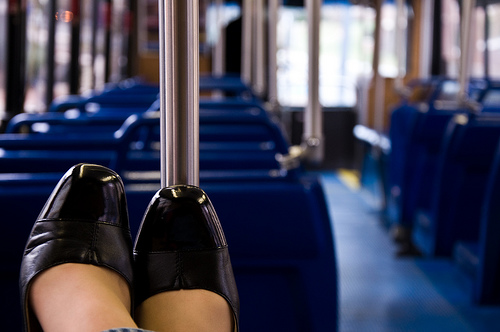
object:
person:
[224, 16, 241, 74]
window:
[276, 7, 378, 107]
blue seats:
[122, 172, 338, 332]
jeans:
[93, 328, 155, 330]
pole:
[459, 0, 476, 94]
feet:
[28, 263, 136, 332]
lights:
[278, 9, 370, 105]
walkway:
[315, 170, 499, 332]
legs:
[395, 227, 423, 255]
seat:
[429, 85, 500, 259]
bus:
[0, 0, 499, 332]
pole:
[159, 0, 202, 185]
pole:
[304, 0, 321, 159]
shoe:
[132, 183, 240, 331]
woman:
[21, 165, 239, 332]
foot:
[140, 288, 228, 332]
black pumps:
[22, 164, 132, 331]